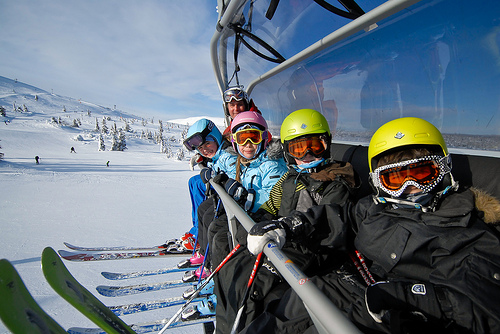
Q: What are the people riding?
A: Ski lift.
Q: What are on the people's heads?
A: Helmets.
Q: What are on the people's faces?
A: Goggles.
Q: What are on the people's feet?
A: Skis.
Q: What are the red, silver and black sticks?
A: Ski poles.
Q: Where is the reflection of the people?
A: Back of ski lift.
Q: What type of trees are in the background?
A: Evergreen.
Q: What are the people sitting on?
A: A ski lift.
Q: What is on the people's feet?
A: Skis.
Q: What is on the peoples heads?
A: Helmets.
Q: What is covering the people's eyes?
A: Goggles.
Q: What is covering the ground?
A: Snow.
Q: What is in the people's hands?
A: Ski poles.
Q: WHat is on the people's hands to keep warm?
A: Gloves.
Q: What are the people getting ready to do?
A: Ski.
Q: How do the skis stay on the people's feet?
A: Boots and binders.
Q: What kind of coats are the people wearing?
A: Ski jackets.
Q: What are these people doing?
A: Skiing.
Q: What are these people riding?
A: A ski lift.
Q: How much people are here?
A: 5.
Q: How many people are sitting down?
A: Five.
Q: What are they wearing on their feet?
A: Skis.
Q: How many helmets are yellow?
A: Two.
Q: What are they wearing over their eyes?
A: Goggles.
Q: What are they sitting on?
A: Ski lift.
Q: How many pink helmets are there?
A: One.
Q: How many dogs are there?
A: None.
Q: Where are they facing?
A: Left.